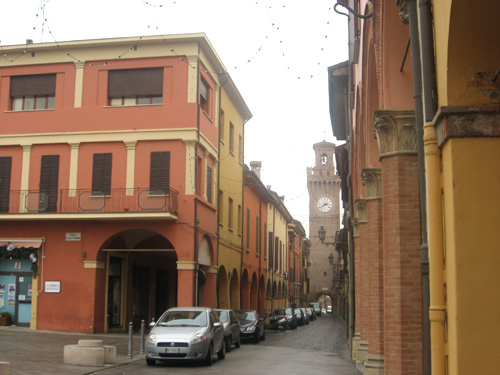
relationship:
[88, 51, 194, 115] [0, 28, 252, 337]
window on building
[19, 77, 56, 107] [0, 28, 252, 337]
window on building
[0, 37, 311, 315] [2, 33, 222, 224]
building has trim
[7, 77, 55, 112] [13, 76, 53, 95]
window has shade